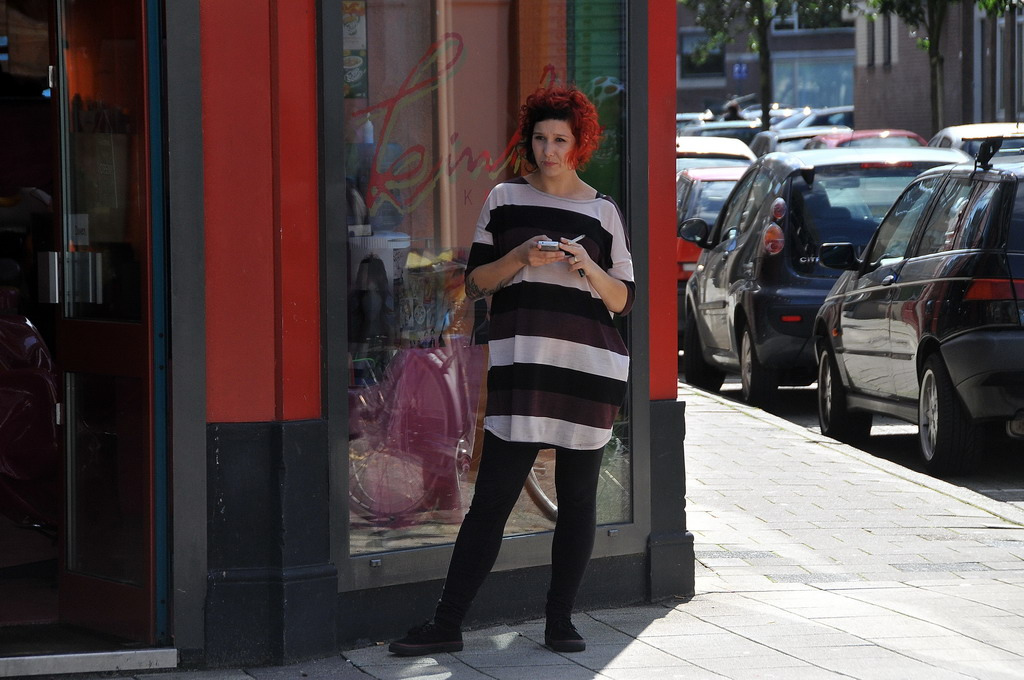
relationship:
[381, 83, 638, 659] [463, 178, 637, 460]
woman wearing shirt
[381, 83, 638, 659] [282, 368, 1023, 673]
woman standing on sidewalk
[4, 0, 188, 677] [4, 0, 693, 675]
door on side of building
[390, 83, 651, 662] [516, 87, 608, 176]
woman has hair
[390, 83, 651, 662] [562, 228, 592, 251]
woman holding cigarette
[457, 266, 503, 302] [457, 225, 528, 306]
tattoo on arm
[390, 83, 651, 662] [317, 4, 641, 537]
woman standing in front of window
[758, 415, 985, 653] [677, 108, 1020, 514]
curb near street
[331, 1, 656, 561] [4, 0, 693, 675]
window on a building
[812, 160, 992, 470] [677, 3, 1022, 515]
car on a street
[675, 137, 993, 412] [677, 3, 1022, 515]
car on a street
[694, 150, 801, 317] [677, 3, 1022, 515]
car on a street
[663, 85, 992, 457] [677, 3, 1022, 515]
car on a street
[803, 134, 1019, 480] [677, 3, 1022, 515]
car on a street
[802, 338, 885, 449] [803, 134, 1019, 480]
tire on a car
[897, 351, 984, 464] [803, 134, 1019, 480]
tire on a car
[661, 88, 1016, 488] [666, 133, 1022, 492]
row of cars